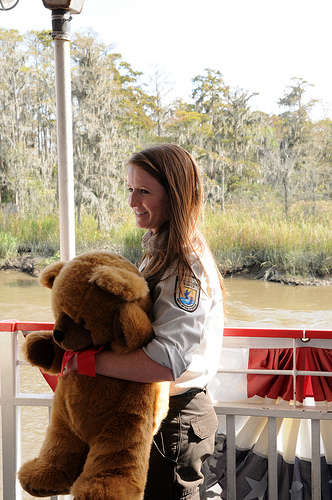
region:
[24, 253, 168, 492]
A large brown teddy bear in the woman's hands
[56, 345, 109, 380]
A red ribbon over the woman's wrist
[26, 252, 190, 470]
The woman is holding a great big teddy bear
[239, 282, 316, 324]
Muddy swamp water behind the woman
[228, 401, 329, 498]
A small white fence behind the woman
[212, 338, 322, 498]
An American flag hanging behind the woman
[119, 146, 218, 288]
The woman has long red hair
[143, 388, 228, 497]
The woman wears black shorts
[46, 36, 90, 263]
A large white pole in the water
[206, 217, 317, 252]
Tall green grass on the shore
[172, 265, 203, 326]
the shhirt has a logo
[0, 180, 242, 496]
the lady is holding a teddy bear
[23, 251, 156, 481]
the teddy bear is brown in colour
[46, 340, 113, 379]
the bear has a red ribbon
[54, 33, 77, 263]
the lampstand is white and long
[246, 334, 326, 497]
the flag has stars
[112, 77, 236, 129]
the trees are tall and do not have many leaves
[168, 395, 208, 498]
the trouser is black in colour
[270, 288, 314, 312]
the river is dirty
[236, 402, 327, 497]
the metal railings are white in colour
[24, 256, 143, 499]
A stuff bear in her hands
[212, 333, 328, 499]
A flag on the railing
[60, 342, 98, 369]
A bowtie on the stuffed bear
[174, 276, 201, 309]
A patch on the left side of her shirt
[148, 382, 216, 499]
The woman is wearing black pants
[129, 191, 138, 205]
The nose of the woman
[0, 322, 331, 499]
A railing behind the woman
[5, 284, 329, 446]
Water below the railing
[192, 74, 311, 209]
Trees across the water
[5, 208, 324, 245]
A grassy area below the trees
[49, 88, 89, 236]
a pole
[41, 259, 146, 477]
a brown teddy bear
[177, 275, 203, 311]
a patch on uniform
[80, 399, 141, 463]
the bear is brown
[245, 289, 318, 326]
the brown water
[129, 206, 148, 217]
the women is smiling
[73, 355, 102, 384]
a red ribbon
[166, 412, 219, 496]
black pants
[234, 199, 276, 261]
the grass is tall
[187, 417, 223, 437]
back pocket on the pants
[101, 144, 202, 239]
head of the lady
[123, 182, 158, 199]
eyes of the lady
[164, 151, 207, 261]
hair on the lady's head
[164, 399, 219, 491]
pants on the lady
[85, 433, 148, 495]
leg of the bear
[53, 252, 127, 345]
head of the bear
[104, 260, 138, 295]
ear of the bear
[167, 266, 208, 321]
symbol on the shirt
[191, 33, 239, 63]
sky above the trees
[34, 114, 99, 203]
pole next to the bear